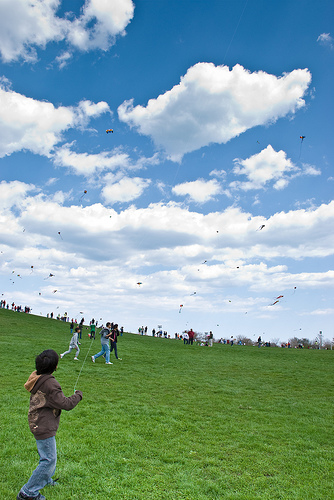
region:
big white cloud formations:
[82, 55, 297, 296]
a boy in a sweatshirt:
[23, 334, 103, 462]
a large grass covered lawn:
[17, 302, 317, 492]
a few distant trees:
[174, 323, 320, 355]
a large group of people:
[1, 308, 288, 362]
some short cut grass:
[130, 388, 310, 476]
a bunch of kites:
[7, 183, 100, 301]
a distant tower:
[315, 330, 330, 355]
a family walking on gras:
[57, 315, 141, 373]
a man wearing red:
[184, 324, 199, 346]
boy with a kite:
[19, 157, 92, 495]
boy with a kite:
[19, 229, 245, 497]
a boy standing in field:
[19, 347, 84, 493]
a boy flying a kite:
[20, 0, 255, 499]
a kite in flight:
[257, 223, 264, 231]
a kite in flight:
[266, 297, 279, 307]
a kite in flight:
[273, 292, 283, 299]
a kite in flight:
[289, 283, 298, 294]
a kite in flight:
[134, 278, 142, 285]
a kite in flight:
[41, 270, 53, 280]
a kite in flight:
[26, 261, 35, 272]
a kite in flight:
[54, 229, 64, 240]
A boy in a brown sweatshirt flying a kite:
[15, 347, 82, 498]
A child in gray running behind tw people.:
[57, 327, 81, 361]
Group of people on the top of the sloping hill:
[0, 298, 33, 314]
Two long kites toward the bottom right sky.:
[268, 293, 282, 307]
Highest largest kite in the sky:
[102, 126, 114, 133]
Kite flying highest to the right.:
[298, 133, 307, 151]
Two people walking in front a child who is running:
[92, 321, 121, 363]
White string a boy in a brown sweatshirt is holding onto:
[74, 326, 101, 393]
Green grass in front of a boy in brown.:
[72, 447, 138, 498]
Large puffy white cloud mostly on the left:
[21, 201, 202, 256]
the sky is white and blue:
[21, 71, 283, 387]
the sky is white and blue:
[42, 173, 266, 326]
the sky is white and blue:
[99, 215, 193, 371]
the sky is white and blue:
[69, 183, 273, 463]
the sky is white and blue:
[112, 256, 248, 433]